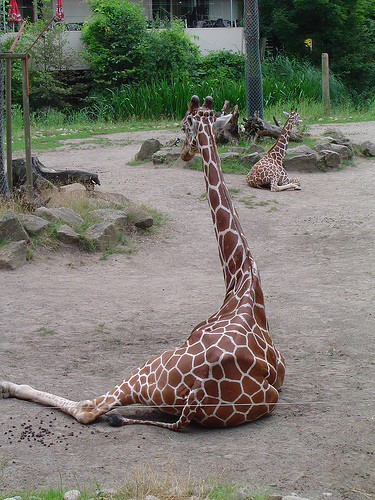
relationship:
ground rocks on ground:
[78, 204, 126, 254] [5, 122, 372, 498]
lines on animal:
[143, 298, 234, 400] [2, 91, 283, 428]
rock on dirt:
[317, 147, 340, 168] [1, 123, 373, 499]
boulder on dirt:
[286, 142, 341, 173] [1, 123, 373, 499]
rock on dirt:
[134, 138, 160, 163] [1, 123, 373, 499]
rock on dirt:
[151, 143, 184, 166] [1, 123, 373, 499]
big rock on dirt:
[54, 223, 77, 245] [1, 123, 373, 499]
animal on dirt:
[245, 106, 302, 192] [139, 172, 370, 225]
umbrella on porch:
[5, 2, 23, 33] [3, 27, 248, 84]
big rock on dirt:
[0, 211, 35, 245] [1, 123, 373, 499]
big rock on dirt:
[0, 211, 48, 269] [1, 123, 373, 499]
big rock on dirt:
[78, 210, 129, 250] [1, 123, 373, 499]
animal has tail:
[245, 106, 302, 192] [101, 389, 210, 436]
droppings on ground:
[0, 411, 75, 451] [5, 122, 372, 498]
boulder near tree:
[286, 136, 354, 173] [236, 0, 270, 136]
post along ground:
[321, 51, 330, 121] [0, 121, 375, 490]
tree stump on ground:
[248, 111, 309, 144] [5, 122, 372, 498]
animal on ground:
[245, 106, 302, 192] [5, 122, 372, 498]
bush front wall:
[74, 16, 198, 94] [169, 15, 251, 80]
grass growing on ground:
[32, 128, 131, 151] [50, 149, 358, 475]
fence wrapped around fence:
[241, 0, 266, 124] [241, 0, 262, 124]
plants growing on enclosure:
[152, 53, 267, 102] [22, 10, 281, 113]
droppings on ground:
[4, 415, 75, 458] [9, 137, 372, 444]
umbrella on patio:
[5, 0, 23, 33] [7, 4, 239, 31]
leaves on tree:
[109, 11, 153, 47] [80, 0, 160, 88]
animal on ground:
[245, 106, 302, 192] [289, 441, 351, 487]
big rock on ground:
[54, 223, 77, 245] [26, 141, 345, 384]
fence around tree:
[241, 0, 262, 124] [240, 0, 266, 116]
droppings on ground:
[0, 411, 75, 451] [279, 157, 371, 491]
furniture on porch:
[195, 19, 221, 27] [1, 17, 246, 70]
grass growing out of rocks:
[1, 194, 167, 274] [28, 202, 129, 253]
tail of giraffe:
[112, 405, 213, 437] [130, 77, 318, 499]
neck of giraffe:
[200, 139, 249, 269] [34, 94, 313, 430]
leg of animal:
[0, 347, 197, 430] [0, 95, 286, 431]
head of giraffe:
[178, 94, 216, 162] [248, 102, 303, 196]